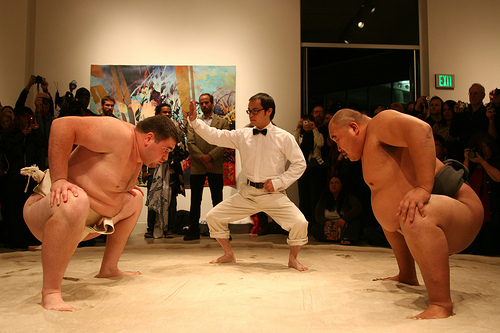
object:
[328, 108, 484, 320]
sumo wrestler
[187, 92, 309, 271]
referee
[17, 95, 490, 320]
wrestlers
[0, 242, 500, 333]
ring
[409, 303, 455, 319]
feet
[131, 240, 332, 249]
sand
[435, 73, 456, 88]
exit sign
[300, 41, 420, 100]
doorway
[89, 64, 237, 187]
picture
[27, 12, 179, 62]
wall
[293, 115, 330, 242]
person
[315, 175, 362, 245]
person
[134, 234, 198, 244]
floor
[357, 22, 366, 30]
lights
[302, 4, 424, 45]
window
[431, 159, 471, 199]
loincloth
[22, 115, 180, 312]
sumo wrestler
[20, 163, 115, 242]
loincloth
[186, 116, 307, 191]
shirt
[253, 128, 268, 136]
bowtie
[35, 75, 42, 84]
camera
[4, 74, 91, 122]
air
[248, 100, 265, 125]
face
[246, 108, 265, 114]
glasses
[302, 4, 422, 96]
nighttime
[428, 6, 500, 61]
wall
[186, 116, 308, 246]
white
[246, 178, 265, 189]
belt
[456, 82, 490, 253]
spectators